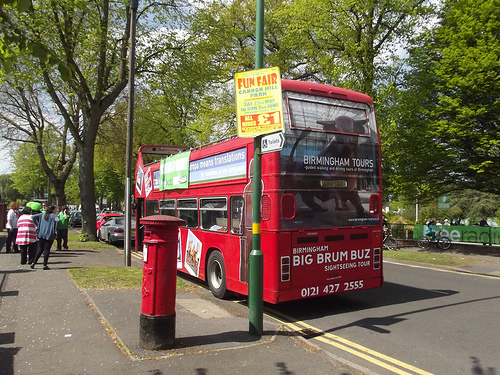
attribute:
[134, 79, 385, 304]
bus — double decker, empty, red, double-decker, british, large, waiting, parked, white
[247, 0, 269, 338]
pole — green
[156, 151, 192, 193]
banner — green, white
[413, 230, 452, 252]
bike — parked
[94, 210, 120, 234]
car — parked, red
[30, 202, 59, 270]
man — standing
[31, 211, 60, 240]
sweater — blue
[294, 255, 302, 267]
letter — white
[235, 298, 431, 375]
lines — yellow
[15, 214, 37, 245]
sweater — striped, white, pink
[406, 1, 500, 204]
tree — green, tall, brown, leafy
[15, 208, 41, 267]
person — standing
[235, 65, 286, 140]
poster — yellow, ad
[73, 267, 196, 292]
grass — green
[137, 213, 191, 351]
trash bin — red